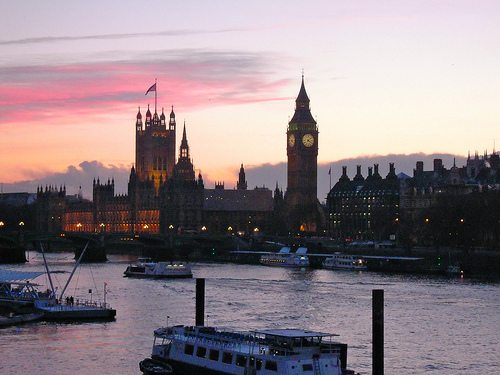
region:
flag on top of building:
[138, 76, 165, 107]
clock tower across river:
[278, 68, 348, 230]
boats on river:
[1, 238, 313, 368]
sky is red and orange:
[14, 51, 148, 188]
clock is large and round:
[278, 120, 322, 168]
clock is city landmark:
[282, 82, 315, 206]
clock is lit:
[283, 131, 315, 174]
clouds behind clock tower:
[235, 127, 439, 186]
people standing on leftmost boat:
[10, 248, 68, 316]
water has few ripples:
[163, 281, 458, 366]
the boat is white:
[126, 298, 256, 373]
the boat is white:
[163, 322, 245, 366]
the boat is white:
[116, 317, 348, 354]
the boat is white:
[137, 322, 195, 349]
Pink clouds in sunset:
[15, 31, 125, 165]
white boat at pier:
[117, 260, 315, 374]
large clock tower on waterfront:
[246, 46, 371, 281]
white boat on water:
[110, 231, 241, 311]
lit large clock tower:
[235, 42, 360, 261]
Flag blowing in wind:
[73, 33, 245, 270]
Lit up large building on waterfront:
[45, 139, 250, 283]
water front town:
[213, 193, 493, 303]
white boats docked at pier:
[238, 219, 442, 306]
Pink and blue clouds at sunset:
[11, 24, 290, 196]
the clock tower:
[281, 57, 328, 220]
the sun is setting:
[22, 38, 122, 161]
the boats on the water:
[72, 247, 361, 373]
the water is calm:
[246, 287, 345, 310]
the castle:
[117, 107, 233, 209]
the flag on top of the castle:
[126, 76, 171, 112]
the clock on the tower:
[298, 131, 320, 148]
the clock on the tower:
[281, 131, 298, 148]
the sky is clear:
[321, 5, 458, 83]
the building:
[336, 160, 499, 245]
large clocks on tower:
[280, 130, 317, 151]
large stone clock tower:
[279, 68, 332, 216]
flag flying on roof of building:
[138, 77, 170, 96]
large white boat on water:
[135, 302, 368, 373]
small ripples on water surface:
[404, 314, 460, 341]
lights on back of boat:
[163, 260, 188, 270]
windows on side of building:
[329, 194, 389, 227]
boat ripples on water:
[224, 276, 279, 296]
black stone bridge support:
[87, 245, 105, 262]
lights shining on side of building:
[136, 160, 174, 195]